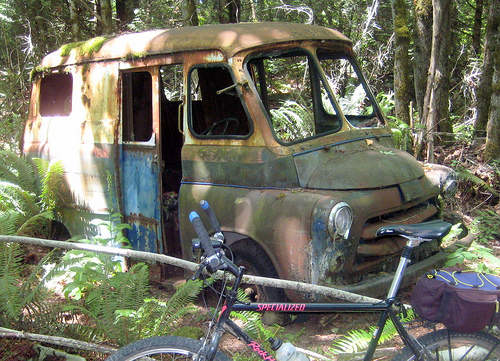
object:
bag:
[410, 268, 500, 334]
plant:
[56, 262, 221, 348]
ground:
[0, 142, 499, 360]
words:
[244, 338, 278, 360]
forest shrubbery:
[0, 151, 251, 360]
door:
[116, 67, 162, 280]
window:
[242, 46, 342, 145]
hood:
[290, 134, 422, 203]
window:
[36, 71, 74, 118]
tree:
[0, 0, 500, 162]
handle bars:
[186, 210, 217, 260]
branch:
[0, 211, 53, 270]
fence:
[0, 234, 413, 358]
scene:
[0, 0, 500, 360]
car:
[22, 21, 475, 327]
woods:
[0, 0, 499, 359]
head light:
[324, 201, 355, 243]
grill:
[344, 197, 441, 277]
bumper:
[283, 229, 471, 303]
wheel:
[226, 235, 306, 328]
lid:
[264, 335, 282, 348]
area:
[350, 183, 416, 210]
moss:
[59, 40, 84, 57]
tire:
[105, 334, 230, 361]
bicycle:
[105, 198, 500, 359]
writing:
[256, 301, 306, 312]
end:
[187, 209, 201, 223]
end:
[199, 199, 211, 211]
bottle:
[268, 337, 311, 360]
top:
[267, 335, 282, 353]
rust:
[116, 210, 156, 231]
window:
[186, 62, 255, 140]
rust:
[174, 57, 219, 71]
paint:
[120, 148, 166, 253]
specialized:
[253, 302, 303, 313]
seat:
[376, 220, 453, 239]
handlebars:
[198, 198, 224, 235]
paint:
[252, 303, 303, 313]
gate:
[0, 232, 412, 360]